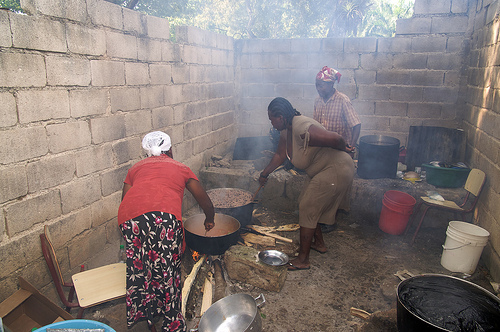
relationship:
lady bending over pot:
[115, 130, 215, 331] [180, 202, 249, 262]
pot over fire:
[178, 206, 247, 262] [175, 167, 298, 286]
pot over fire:
[201, 187, 254, 229] [175, 167, 298, 286]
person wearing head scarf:
[313, 61, 363, 158] [316, 63, 341, 85]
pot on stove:
[201, 187, 254, 229] [184, 248, 217, 304]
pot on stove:
[181, 210, 242, 255] [184, 248, 217, 304]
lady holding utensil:
[115, 130, 215, 331] [204, 227, 210, 236]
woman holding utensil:
[263, 97, 351, 267] [245, 176, 276, 203]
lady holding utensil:
[115, 130, 215, 331] [203, 227, 210, 234]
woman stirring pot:
[263, 97, 351, 267] [201, 187, 254, 229]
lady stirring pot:
[115, 130, 215, 331] [187, 210, 240, 257]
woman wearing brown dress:
[258, 97, 357, 271] [283, 138, 358, 213]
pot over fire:
[196, 183, 259, 237] [185, 245, 211, 263]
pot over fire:
[181, 210, 242, 255] [185, 245, 211, 263]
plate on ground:
[259, 249, 291, 267] [36, 200, 498, 330]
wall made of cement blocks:
[1, 5, 236, 280] [15, 88, 72, 123]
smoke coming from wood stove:
[188, 6, 374, 138] [192, 113, 422, 199]